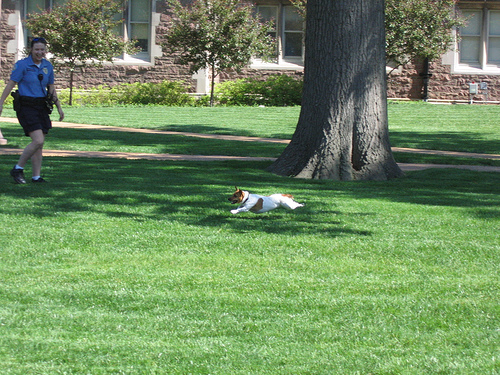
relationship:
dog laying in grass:
[228, 186, 305, 214] [1, 100, 499, 371]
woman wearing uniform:
[2, 35, 62, 185] [12, 57, 54, 134]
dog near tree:
[227, 185, 302, 214] [264, 4, 402, 186]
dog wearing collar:
[227, 185, 302, 214] [241, 193, 251, 209]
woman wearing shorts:
[2, 35, 62, 185] [12, 92, 51, 136]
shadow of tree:
[12, 121, 497, 241] [264, 4, 402, 186]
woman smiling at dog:
[0, 38, 65, 184] [221, 182, 308, 219]